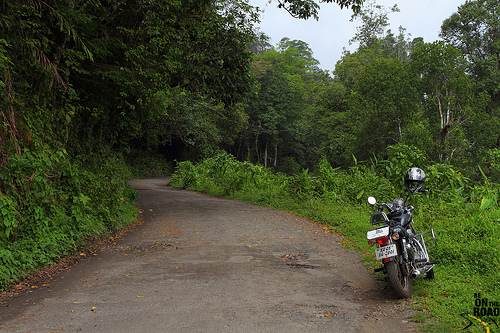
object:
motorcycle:
[367, 189, 441, 298]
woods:
[93, 0, 499, 168]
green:
[183, 162, 261, 194]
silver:
[404, 167, 426, 181]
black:
[388, 266, 393, 279]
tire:
[384, 252, 412, 298]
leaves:
[18, 203, 89, 247]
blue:
[317, 22, 336, 52]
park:
[0, 0, 499, 331]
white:
[377, 257, 382, 260]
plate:
[375, 244, 398, 260]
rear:
[366, 211, 412, 297]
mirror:
[368, 196, 377, 204]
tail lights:
[376, 236, 388, 245]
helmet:
[404, 167, 427, 195]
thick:
[67, 135, 168, 167]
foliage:
[28, 67, 117, 225]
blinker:
[392, 233, 400, 240]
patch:
[242, 129, 348, 178]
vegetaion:
[225, 117, 340, 208]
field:
[166, 172, 500, 332]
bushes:
[10, 139, 123, 232]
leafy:
[134, 49, 242, 106]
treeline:
[197, 0, 499, 181]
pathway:
[0, 174, 417, 332]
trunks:
[251, 135, 277, 166]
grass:
[438, 231, 498, 309]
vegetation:
[332, 162, 400, 197]